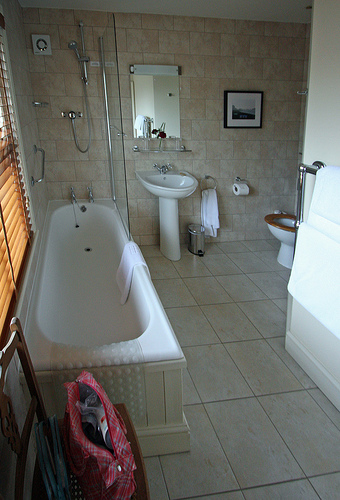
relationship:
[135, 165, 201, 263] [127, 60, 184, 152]
sink under mirror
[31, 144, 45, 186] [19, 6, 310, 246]
rack attached to wall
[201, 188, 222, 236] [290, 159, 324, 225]
towel on rack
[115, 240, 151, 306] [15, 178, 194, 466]
towel over bathtub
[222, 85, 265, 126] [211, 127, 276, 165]
picture on wall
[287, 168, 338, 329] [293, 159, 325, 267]
towels hanging on rack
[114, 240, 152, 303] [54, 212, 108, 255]
towel hanging over tub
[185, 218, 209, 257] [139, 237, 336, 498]
trash can on floor